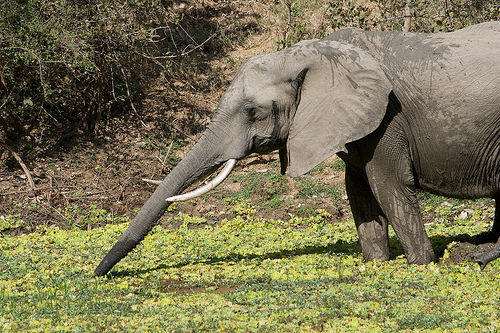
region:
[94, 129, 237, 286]
long grey elephant trunk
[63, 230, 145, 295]
wet tip to trunk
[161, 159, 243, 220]
long white horn of elephant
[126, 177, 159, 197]
tip of ivory horn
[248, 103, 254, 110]
large black eye of elephant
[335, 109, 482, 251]
wet body of elpehant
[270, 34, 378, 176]
large grey ear of elephant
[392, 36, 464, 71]
shadow on top of body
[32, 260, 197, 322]
wetlands with bushes in it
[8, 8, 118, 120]
bushes and leaves on side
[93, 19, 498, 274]
large grey elephant is standing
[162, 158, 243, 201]
white tusk in front of gray trunk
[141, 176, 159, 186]
sharp tusk behind trunk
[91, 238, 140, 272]
wet area on trunk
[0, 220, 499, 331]
grass under elephant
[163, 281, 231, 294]
bare brown patch surrounded by grass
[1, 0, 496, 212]
hill behind elephant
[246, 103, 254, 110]
dark eye is open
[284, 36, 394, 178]
elephant has a floppy gray ear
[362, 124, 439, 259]
leg is wet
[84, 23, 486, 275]
an elephant that is outside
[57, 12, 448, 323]
a large elephant that is outside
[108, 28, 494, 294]
an old elephant outisde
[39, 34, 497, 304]
a large old elephant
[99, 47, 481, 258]
an elephant standing in grass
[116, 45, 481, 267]
an old elephant standing in grass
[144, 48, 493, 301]
an elephant with long tusks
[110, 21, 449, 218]
an old elephant with long tusks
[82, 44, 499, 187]
a large elephant with long tusks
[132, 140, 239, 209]
white tusks on elephant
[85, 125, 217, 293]
grey elephant trunk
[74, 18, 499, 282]
grey elephant in green field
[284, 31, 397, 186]
grey elephant ear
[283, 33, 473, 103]
water stain on elephant back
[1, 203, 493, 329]
green grass field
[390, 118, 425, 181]
wrinkled texture of elephant skin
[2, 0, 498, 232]
dirt hill behind elephant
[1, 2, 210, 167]
green brush and bushes on side of green grass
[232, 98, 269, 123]
one elephant eye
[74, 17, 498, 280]
This is an elephant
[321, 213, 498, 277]
The elephant is submerged in mud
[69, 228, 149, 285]
The elephant is drinking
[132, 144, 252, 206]
The elephant has large white tusks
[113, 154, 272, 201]
The tusks are made of ivory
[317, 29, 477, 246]
The elephant has water all over it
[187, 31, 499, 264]
The left side of the elephant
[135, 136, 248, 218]
The tusks are very sharp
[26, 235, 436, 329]
The muddy water is covered by a green substance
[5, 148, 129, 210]
A number of sticks on the ground